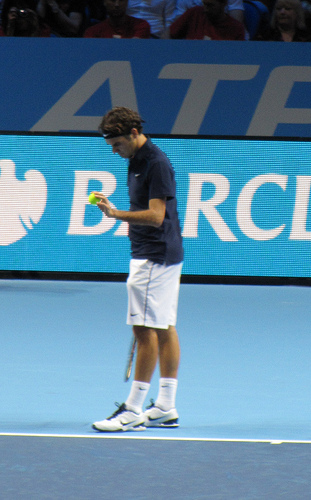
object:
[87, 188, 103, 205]
tennis ball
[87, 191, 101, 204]
ball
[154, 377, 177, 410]
sock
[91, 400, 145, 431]
shoe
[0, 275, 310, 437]
court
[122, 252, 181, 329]
short pants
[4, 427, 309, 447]
white line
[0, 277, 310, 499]
blue court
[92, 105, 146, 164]
head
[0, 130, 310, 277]
sign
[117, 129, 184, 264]
blue shirt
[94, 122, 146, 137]
headband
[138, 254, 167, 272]
pocket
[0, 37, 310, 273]
blue wall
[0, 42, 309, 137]
white logo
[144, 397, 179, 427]
shoe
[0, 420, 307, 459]
lines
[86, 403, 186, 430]
shoes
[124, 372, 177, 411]
nike socks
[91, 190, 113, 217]
hand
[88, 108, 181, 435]
player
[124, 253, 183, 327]
tennis shorts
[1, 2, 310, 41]
crowd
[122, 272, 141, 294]
bulge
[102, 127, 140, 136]
headband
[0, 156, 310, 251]
logo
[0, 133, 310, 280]
wall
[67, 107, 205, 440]
man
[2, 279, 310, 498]
court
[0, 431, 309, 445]
line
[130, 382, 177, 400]
white socks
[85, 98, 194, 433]
athlete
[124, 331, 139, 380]
racket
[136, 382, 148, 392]
logo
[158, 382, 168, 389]
logo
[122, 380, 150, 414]
sock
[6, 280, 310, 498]
tennis court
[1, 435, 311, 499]
court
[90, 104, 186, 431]
tennis player